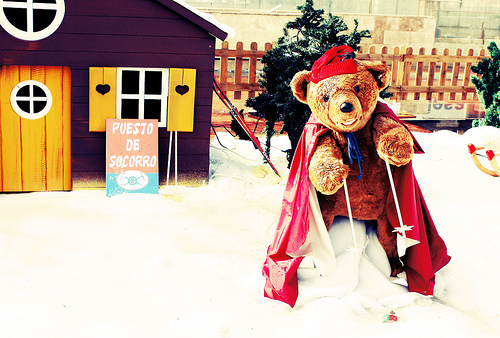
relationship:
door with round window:
[1, 65, 71, 192] [8, 81, 53, 119]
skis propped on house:
[208, 71, 282, 179] [79, 4, 243, 210]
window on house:
[115, 68, 170, 126] [0, 2, 231, 188]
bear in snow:
[255, 29, 452, 336] [2, 137, 497, 332]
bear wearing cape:
[284, 44, 419, 334] [278, 119, 446, 320]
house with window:
[0, 0, 231, 188] [115, 68, 170, 126]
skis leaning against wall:
[208, 43, 290, 180] [196, 41, 211, 181]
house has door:
[0, 0, 231, 188] [1, 64, 78, 194]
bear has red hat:
[284, 44, 419, 334] [305, 44, 359, 84]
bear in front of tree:
[284, 44, 419, 334] [252, 0, 382, 177]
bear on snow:
[284, 44, 419, 334] [44, 130, 461, 330]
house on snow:
[0, 2, 231, 188] [44, 130, 461, 330]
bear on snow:
[284, 44, 419, 334] [259, 45, 452, 307]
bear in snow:
[284, 44, 419, 334] [49, 228, 372, 335]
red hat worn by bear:
[302, 39, 370, 84] [284, 44, 419, 334]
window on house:
[115, 63, 167, 127] [0, 2, 231, 188]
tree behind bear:
[247, 1, 396, 168] [284, 44, 419, 334]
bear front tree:
[284, 44, 419, 334] [458, 38, 498, 139]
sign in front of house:
[102, 118, 160, 192] [0, 2, 231, 188]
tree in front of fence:
[468, 40, 499, 132] [216, 40, 491, 104]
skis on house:
[208, 71, 282, 179] [45, 34, 200, 192]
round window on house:
[6, 80, 52, 117] [0, 2, 231, 188]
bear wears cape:
[284, 44, 419, 334] [259, 101, 453, 307]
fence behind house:
[216, 45, 498, 107] [0, 2, 231, 188]